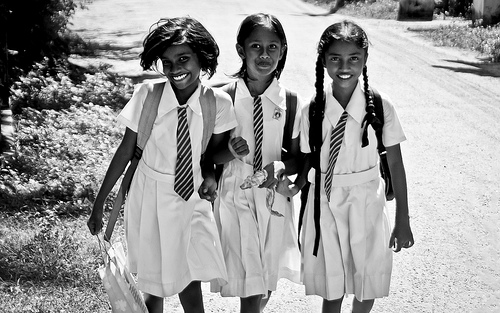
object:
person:
[300, 21, 412, 310]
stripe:
[175, 114, 193, 178]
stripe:
[256, 134, 263, 154]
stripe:
[329, 136, 339, 156]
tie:
[253, 95, 264, 174]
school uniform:
[296, 90, 405, 299]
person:
[198, 9, 306, 311]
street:
[411, 41, 497, 311]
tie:
[323, 111, 347, 202]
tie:
[172, 105, 194, 201]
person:
[87, 14, 235, 311]